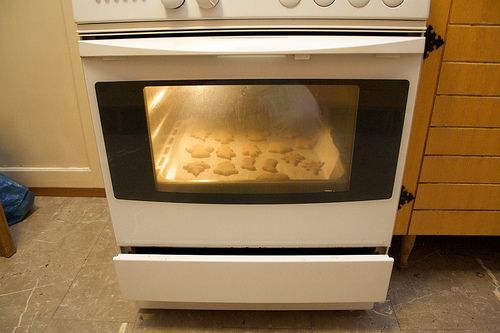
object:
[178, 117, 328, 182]
cookies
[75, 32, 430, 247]
white oven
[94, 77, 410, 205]
oven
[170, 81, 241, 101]
light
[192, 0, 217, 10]
knobs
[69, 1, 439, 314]
stove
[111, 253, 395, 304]
drawer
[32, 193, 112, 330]
tile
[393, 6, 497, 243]
cabinets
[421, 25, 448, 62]
hinges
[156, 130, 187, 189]
silver tray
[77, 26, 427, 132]
window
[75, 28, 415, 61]
door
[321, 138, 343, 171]
wax paper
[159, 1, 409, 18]
knobs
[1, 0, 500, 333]
kitchen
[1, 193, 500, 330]
linoleum floor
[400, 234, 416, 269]
wood leg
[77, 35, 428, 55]
handle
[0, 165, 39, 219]
bag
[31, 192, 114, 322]
floor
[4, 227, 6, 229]
wooden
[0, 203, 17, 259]
leg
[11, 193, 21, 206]
fabric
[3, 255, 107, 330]
ground